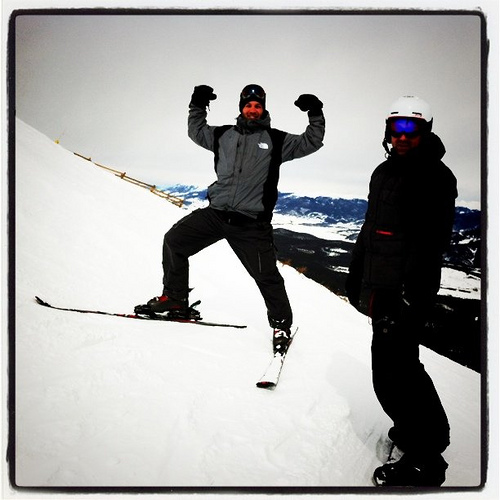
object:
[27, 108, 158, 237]
hill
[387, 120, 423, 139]
goggles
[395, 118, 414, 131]
blue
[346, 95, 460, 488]
man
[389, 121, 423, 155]
face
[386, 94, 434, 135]
helmet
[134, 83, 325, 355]
man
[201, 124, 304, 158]
muscles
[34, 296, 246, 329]
skis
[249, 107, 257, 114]
red nose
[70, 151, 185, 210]
fence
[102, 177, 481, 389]
mountains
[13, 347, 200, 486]
snow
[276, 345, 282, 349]
snow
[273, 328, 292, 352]
man's foot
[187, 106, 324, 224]
jacket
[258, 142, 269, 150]
logo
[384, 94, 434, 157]
head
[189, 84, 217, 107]
glove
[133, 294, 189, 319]
boot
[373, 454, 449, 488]
boot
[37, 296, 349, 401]
ski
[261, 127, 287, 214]
black line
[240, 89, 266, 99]
goggles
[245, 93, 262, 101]
forehead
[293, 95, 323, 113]
left hand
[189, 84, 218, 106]
right hand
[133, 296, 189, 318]
right foot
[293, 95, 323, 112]
glove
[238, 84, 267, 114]
black hat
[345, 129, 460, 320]
black jacket